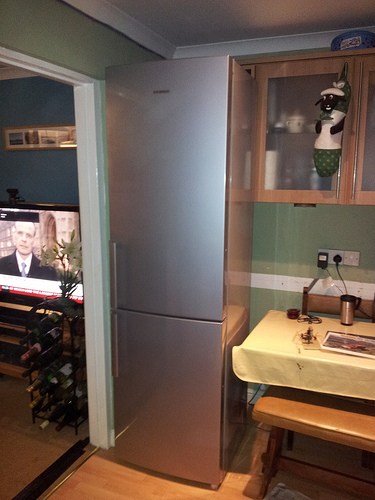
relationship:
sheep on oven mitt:
[307, 83, 352, 114] [311, 59, 347, 182]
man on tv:
[1, 222, 44, 272] [0, 205, 98, 303]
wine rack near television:
[22, 295, 89, 428] [0, 205, 98, 303]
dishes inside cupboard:
[267, 109, 338, 203] [239, 63, 375, 211]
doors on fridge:
[110, 76, 213, 481] [116, 69, 237, 474]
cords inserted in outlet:
[311, 248, 344, 291] [318, 250, 357, 269]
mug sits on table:
[334, 290, 362, 342] [254, 314, 373, 499]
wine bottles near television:
[17, 310, 69, 428] [0, 205, 98, 303]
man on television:
[1, 222, 44, 272] [0, 205, 98, 303]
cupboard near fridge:
[239, 63, 375, 211] [116, 69, 237, 474]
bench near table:
[251, 374, 373, 481] [254, 314, 373, 499]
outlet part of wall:
[318, 250, 357, 269] [242, 198, 367, 277]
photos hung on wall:
[7, 124, 79, 157] [1, 86, 72, 200]